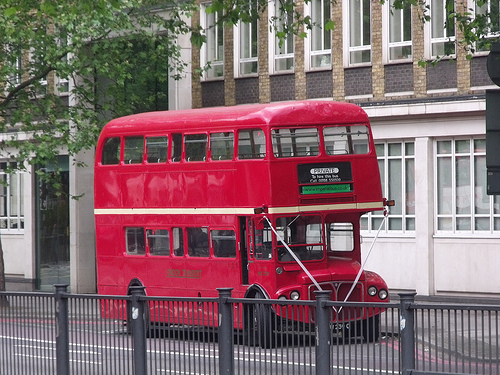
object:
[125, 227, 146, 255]
window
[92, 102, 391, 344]
bus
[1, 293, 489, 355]
pavement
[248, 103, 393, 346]
frontal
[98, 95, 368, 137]
roof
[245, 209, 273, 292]
door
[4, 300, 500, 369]
street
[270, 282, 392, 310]
lights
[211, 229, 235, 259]
windows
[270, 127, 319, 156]
window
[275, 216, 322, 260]
window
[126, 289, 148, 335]
wheel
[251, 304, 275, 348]
wheel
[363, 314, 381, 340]
wheel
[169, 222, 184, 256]
side window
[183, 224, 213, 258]
side window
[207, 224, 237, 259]
side window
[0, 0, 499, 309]
building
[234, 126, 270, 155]
window